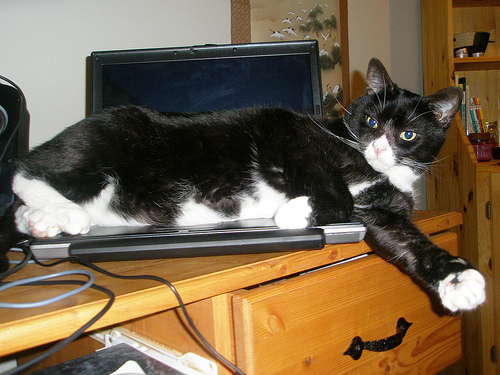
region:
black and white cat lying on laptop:
[8, 53, 490, 315]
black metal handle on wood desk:
[342, 316, 414, 363]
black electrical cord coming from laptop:
[26, 241, 131, 280]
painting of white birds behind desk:
[231, 4, 350, 53]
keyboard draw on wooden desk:
[58, 329, 205, 371]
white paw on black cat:
[434, 265, 492, 316]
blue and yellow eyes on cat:
[394, 127, 421, 144]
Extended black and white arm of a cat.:
[367, 207, 484, 312]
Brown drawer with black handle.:
[232, 231, 464, 373]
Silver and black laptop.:
[27, 39, 366, 259]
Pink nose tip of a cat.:
[371, 144, 386, 157]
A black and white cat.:
[10, 58, 486, 313]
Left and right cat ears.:
[363, 56, 461, 130]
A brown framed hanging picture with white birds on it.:
[227, 1, 349, 116]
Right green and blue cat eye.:
[365, 112, 379, 129]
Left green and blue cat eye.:
[399, 130, 416, 140]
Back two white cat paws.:
[12, 164, 92, 239]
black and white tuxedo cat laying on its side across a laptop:
[11, 56, 486, 311]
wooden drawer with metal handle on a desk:
[215, 230, 460, 372]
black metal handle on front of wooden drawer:
[342, 315, 412, 361]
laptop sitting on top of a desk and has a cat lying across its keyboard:
[30, 38, 367, 263]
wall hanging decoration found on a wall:
[229, 0, 349, 125]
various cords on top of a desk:
[1, 243, 248, 374]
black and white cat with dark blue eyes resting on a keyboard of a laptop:
[7, 58, 486, 313]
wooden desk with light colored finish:
[1, 208, 465, 373]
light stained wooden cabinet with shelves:
[419, 0, 497, 373]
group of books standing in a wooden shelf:
[452, 71, 486, 133]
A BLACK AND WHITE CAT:
[2, 54, 495, 319]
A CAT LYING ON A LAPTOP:
[3, 35, 490, 315]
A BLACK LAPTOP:
[25, 35, 370, 270]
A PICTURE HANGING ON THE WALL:
[226, 0, 353, 120]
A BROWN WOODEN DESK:
[2, 205, 472, 370]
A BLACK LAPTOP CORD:
[23, 236, 244, 371]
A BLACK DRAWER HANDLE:
[336, 312, 416, 362]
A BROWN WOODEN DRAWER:
[223, 221, 469, 371]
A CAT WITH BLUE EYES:
[5, 53, 487, 317]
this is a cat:
[25, 24, 450, 307]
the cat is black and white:
[98, 129, 408, 291]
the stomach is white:
[67, 164, 262, 244]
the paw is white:
[376, 259, 498, 329]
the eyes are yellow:
[348, 102, 453, 163]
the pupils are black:
[345, 99, 411, 146]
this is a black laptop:
[54, 44, 219, 166]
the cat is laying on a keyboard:
[88, 110, 283, 237]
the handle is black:
[293, 282, 431, 365]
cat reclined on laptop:
[11, 38, 488, 313]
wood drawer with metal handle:
[233, 232, 464, 372]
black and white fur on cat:
[13, 57, 488, 314]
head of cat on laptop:
[352, 55, 457, 183]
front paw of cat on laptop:
[429, 262, 487, 315]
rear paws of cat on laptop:
[13, 165, 83, 244]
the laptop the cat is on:
[33, 31, 378, 257]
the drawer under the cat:
[218, 199, 477, 374]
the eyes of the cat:
[366, 116, 414, 141]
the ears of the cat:
[364, 48, 462, 129]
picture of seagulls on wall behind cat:
[230, 2, 351, 107]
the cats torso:
[119, 102, 279, 226]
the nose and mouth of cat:
[368, 141, 390, 171]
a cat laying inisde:
[76, 100, 382, 275]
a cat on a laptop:
[73, 45, 295, 265]